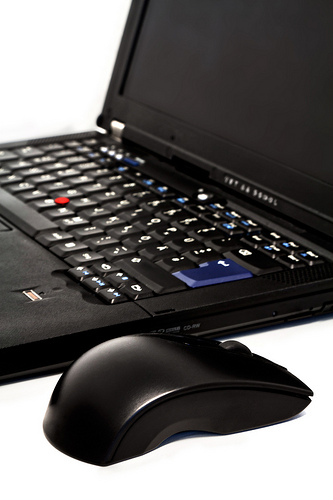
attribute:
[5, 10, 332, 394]
computer — black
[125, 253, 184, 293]
shift key — black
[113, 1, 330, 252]
screen — laptop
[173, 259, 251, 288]
button — blue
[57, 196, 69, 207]
cursor — red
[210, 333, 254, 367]
mouse wheel — black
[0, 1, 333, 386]
laptop — black, computer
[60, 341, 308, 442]
computer mouse — black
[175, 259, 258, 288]
key — blue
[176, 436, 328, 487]
table — white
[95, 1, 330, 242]
monitor — black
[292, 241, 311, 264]
button — white, black 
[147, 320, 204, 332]
writing — white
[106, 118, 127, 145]
hinges — silver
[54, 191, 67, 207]
pointing stick — red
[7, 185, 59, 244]
spacebar — black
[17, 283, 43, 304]
print scanner — finger print